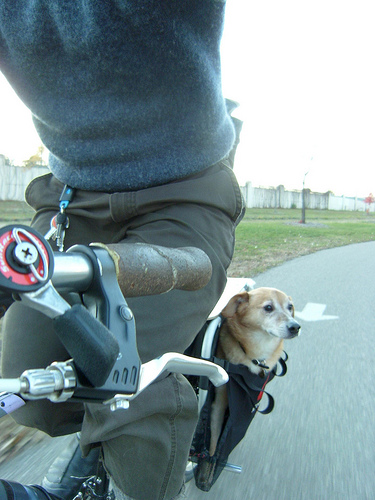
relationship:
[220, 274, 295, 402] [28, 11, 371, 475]
dog in photo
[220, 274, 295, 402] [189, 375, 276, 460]
dog in bag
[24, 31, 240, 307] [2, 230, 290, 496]
person on bike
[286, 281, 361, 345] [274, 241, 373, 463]
arrow in street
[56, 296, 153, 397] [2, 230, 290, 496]
grip on bike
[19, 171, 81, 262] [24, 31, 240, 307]
keys on person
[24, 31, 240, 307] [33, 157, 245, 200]
person has waist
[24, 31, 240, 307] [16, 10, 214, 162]
person wearing sweater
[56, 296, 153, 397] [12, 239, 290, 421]
grip on bike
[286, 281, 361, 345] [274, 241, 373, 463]
arrow on street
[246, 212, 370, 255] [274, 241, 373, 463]
grass by street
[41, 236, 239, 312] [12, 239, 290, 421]
handle on bike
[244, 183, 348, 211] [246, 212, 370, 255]
fence by grass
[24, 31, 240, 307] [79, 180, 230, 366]
person wearing pants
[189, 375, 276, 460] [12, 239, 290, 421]
bag on bike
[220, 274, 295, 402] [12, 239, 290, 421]
dog on bike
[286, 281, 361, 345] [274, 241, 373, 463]
arrow on pavement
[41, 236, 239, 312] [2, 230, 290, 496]
handle on bike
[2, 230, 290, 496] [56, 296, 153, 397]
bike has grip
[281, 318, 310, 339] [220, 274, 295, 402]
nose on dog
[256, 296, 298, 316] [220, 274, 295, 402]
eyes on dog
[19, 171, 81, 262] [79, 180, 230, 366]
keys on pants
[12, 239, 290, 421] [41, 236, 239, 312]
bike has handle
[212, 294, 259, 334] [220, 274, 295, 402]
ears on dog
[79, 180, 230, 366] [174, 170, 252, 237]
pants has pocket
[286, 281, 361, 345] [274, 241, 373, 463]
arrow on road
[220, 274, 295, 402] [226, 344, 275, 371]
dog has collar